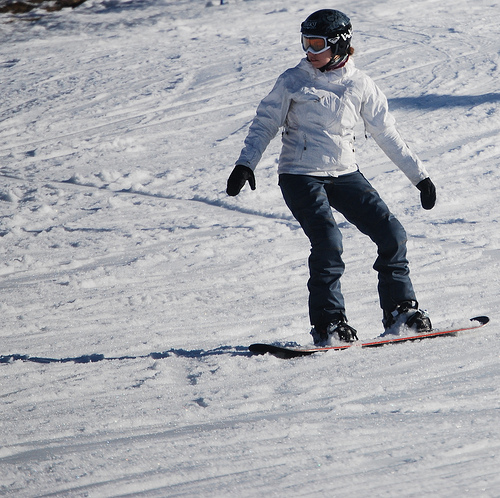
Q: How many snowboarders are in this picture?
A: One.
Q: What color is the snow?
A: White.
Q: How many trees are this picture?
A: Zero.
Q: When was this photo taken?
A: Daytime.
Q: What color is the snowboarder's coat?
A: White.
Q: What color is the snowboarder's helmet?
A: Black.